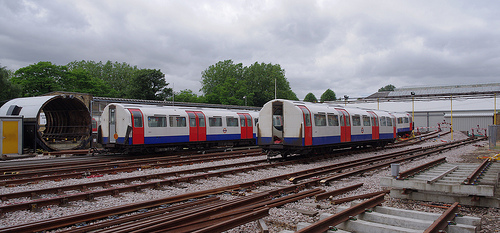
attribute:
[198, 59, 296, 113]
trees — large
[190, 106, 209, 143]
doors — red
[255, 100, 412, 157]
train — parked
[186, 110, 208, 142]
double doors — red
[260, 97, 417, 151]
train car — red, white, blue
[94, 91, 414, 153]
trains — operating safely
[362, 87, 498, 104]
building — large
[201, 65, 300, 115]
trees — green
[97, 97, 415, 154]
trains/locomotives — big, powerful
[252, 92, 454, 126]
train —  on time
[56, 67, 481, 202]
trains — transporting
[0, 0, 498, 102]
sky — grey, overcast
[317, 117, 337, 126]
vacationers — happy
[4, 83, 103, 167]
object — large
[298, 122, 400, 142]
doors — red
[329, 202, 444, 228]
railroad ties — cement